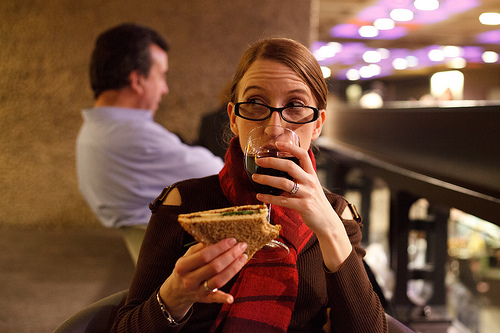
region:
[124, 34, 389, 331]
Woman holding a half of a sandwich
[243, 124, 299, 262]
Glass of red wine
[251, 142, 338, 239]
Woman's hand with a wedding ring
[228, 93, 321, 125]
Two eyes behind a pair of black rimmed glasses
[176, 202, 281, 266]
Half a sandwich with one bite missing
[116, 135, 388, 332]
Brown ribbed sweater paired with an orange and brown scarf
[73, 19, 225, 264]
Man leaning back in a chair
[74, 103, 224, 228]
Light blue man's shirt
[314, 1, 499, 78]
Multitude of ceiling lights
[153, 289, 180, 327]
Silver watch witha black face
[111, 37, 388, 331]
Woman sitting on a chair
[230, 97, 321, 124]
Glasses on the woman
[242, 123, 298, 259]
Wine glass in the woman's left hand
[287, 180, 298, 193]
Ring on the woman's left hand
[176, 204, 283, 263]
Sandwich in the woman's right hand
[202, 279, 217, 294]
Ring on the woman's right hand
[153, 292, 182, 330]
Bracelet on the woman's wrist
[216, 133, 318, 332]
Scarf on the woman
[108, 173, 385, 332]
Shirt on the woman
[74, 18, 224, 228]
Man sitting on a chair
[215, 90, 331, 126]
a pair of brown glasses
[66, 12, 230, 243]
a man relaxing in his chair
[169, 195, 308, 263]
a sandwich with one bite missing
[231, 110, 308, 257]
a glass of wine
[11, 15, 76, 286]
a wall in the background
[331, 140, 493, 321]
a brown railing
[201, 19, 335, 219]
a woman with red hair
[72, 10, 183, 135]
a man with dark hair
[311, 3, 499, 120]
lighting in a room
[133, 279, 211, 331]
a bracelet on a woman's arm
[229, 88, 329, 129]
pair of black metal eye glasses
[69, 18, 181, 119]
man with short hair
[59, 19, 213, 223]
man in white shirt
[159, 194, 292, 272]
sandwich being held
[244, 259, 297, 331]
red and black scarf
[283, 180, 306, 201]
silver ring on hand of woman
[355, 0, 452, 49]
row of lights on ceiling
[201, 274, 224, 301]
gold ring on finger of woman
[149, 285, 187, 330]
metal bracelet on wrist of woman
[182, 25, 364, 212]
woman with brown hair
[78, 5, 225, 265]
This is a person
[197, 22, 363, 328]
This is a person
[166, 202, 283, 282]
sandwich held in right hand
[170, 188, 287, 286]
sandwich held in right hand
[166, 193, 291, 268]
sandwich held in right hand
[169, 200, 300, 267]
sandwich held in right hand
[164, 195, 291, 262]
sandwich held in right hand